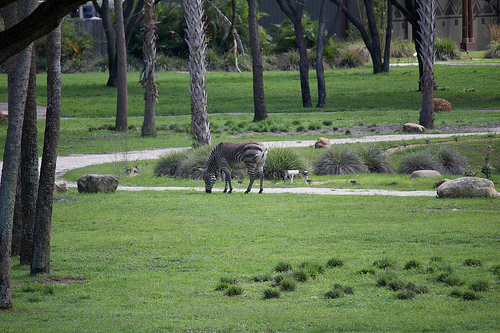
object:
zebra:
[193, 140, 269, 193]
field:
[57, 132, 499, 190]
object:
[283, 165, 300, 182]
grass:
[61, 135, 500, 191]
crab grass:
[215, 246, 500, 315]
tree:
[406, 0, 447, 134]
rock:
[77, 172, 122, 195]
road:
[2, 129, 500, 175]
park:
[0, 51, 496, 331]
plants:
[266, 10, 368, 69]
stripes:
[219, 143, 247, 163]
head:
[196, 163, 218, 196]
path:
[49, 175, 438, 208]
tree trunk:
[314, 0, 329, 108]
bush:
[158, 146, 215, 178]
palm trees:
[174, 0, 220, 147]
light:
[409, 49, 419, 65]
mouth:
[203, 187, 214, 195]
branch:
[2, 0, 92, 66]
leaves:
[283, 33, 297, 40]